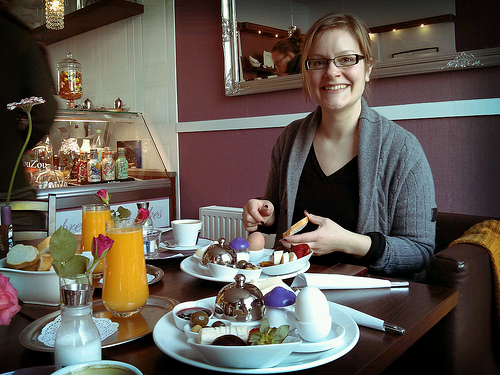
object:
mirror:
[387, 7, 459, 44]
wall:
[175, 5, 499, 270]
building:
[6, 3, 489, 374]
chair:
[411, 190, 495, 262]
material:
[483, 225, 498, 244]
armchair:
[436, 221, 499, 342]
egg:
[245, 230, 266, 250]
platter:
[178, 248, 308, 281]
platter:
[17, 295, 177, 346]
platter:
[150, 290, 362, 373]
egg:
[295, 284, 331, 343]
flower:
[1, 87, 48, 207]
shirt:
[295, 146, 362, 233]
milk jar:
[55, 284, 97, 370]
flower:
[85, 233, 117, 257]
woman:
[240, 10, 436, 271]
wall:
[44, 0, 498, 233]